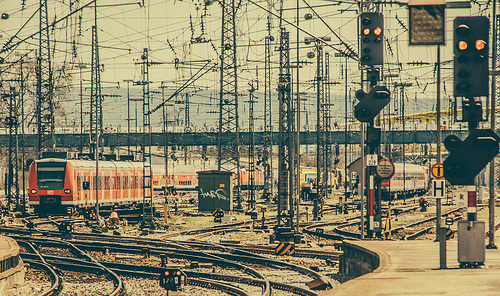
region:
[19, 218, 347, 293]
a complex array of tracks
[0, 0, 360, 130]
wires and towers galore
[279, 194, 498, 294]
a platform for mounting and dismounting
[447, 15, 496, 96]
a double warning of caution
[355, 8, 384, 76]
another double caution warning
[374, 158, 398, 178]
a sign among the confusion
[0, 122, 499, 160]
a long pedestrian walkway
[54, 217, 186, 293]
two signals near ground level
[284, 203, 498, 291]
platform with a curve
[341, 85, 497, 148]
something yellow in the distance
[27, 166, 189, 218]
the train is orange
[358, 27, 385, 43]
orange traffic light is orange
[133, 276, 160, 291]
the gravel is between the tracks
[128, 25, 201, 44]
electric wires above the train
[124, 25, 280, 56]
the sky is cloudy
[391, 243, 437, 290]
the ground is made of concrete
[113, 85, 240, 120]
the hill is in the background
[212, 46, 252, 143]
structures are made of steel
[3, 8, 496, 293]
its daylight in the photo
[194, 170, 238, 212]
the metallic box is grey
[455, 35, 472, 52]
orange light on black base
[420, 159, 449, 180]
yellow sign with black picture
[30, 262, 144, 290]
pieces of black train tracks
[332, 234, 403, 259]
edge of train platform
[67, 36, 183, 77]
large overhead electrical grids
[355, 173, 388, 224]
red and white pole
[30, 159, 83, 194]
black and white front of train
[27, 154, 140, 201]
orange train with white lines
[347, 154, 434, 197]
brown building with white base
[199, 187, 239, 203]
white graffiti on green building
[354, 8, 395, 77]
Traffic light showing red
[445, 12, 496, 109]
Traffic light showing red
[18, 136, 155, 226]
Orange and black train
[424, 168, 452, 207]
White sign with black lettering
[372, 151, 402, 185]
Red and white sign with black lettering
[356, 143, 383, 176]
White sign with black lettering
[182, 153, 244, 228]
Power transformer with graffiti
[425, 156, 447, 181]
Orange and red sign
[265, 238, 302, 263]
Yellow and black painted concrete base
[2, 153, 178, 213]
Train on tracks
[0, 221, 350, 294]
the tracks look like a tangled mess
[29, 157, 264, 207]
the train is orange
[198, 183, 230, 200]
graffiti is on the power box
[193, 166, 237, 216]
the power box is green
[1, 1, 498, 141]
many power lines are above the trains and tracks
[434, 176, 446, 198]
the letter h appears on a white sign on the right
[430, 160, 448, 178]
yellow round sign above white square sign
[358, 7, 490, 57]
the lights are yellow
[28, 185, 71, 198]
two lights are on the trains engine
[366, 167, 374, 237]
the pole is wrapped white and red reflective tape